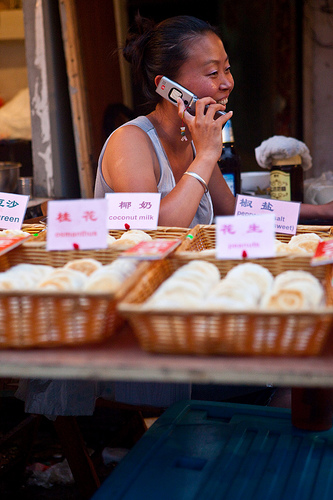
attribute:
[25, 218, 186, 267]
basket — wicker, brown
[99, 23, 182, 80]
bun —  hair style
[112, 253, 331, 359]
basket — wicker, brown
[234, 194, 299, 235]
sign — small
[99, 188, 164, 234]
sign — small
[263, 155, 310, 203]
jar —  Yellow and brown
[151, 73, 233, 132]
phone —  Flip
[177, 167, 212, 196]
bracelet —  Silver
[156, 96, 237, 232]
arm —   woman's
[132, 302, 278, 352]
basket —  weaved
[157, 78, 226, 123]
cell phone —  Lady's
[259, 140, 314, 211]
liquid —  brown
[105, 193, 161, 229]
label —  pink and purple,  Coconut milk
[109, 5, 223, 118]
hair —  Brunette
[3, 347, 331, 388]
table —  White 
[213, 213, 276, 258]
food label —  pink,  5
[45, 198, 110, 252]
food label —  pink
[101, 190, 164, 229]
food label —  pink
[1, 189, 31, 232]
food label —  pink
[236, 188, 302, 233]
food label —  pink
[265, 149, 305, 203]
jar —  Brown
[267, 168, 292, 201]
label —  yellow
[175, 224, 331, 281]
bascket —  weaved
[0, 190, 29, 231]
sign — small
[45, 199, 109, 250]
sign — small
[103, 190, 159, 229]
sign — small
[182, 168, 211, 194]
metal bracelet —  metal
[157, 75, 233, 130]
cellphone —   Silver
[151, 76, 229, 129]
phone — cellular , flip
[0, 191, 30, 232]
label — for food,  Pink and green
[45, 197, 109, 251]
label — for food,  Pink and green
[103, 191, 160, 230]
label — for food,  Pink and green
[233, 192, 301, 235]
label — for food,  Pink and green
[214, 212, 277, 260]
label — for food,  Pink and green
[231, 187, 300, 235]
sign — Pink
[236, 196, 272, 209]
letters —  blue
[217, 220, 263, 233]
letters —  red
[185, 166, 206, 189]
bracelet —   Silver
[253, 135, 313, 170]
rag —  White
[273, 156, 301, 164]
top — jar's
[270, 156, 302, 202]
jar —  clear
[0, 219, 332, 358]
desserts —  sweets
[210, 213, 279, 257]
sign — small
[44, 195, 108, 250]
sign — small,  Pink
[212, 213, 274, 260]
sign — small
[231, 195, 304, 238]
sign — small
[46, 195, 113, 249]
sign — small